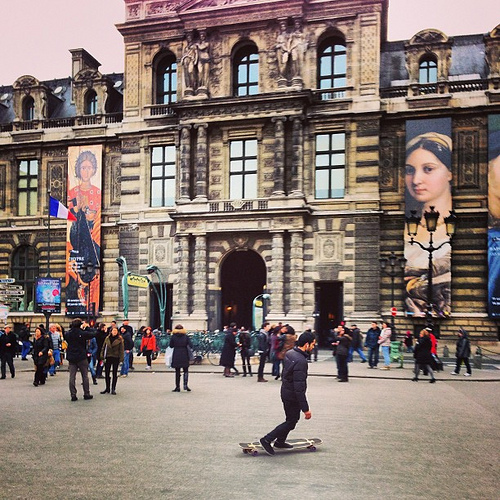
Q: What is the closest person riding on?
A: Skateboard.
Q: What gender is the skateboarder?
A: Male.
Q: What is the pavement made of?
A: Concrete.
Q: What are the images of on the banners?
A: Different women.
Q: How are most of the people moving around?
A: Walking.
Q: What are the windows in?
A: Building.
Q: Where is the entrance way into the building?
A: Middle of the image.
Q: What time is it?
A: Afternoon.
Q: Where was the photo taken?
A: Outside somewhere.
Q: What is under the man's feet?
A: A skateboard.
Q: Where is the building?
A: Behind the people.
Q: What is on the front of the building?
A: Flag pole.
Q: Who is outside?
A: Many people.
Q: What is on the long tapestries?
A: Pictures of art.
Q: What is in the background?
A: A historic building.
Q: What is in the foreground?
A: Several people.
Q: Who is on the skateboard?
A: A young man.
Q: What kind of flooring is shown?
A: Brick paved ground.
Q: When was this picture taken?
A: During the evening.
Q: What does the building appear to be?
A: A museum.